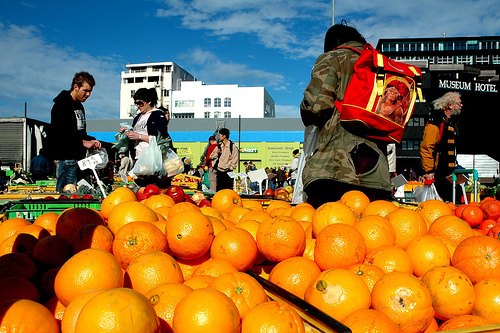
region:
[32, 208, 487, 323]
a lot of oranges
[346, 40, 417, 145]
a red and yellow book bag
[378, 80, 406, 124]
a character from Small Soldiers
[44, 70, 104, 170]
a man in a black hoodie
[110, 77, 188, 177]
a woman carrying several bags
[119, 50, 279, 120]
a white building in the background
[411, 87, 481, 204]
a old man holding grocery bags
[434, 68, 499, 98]
a sign reading Museum Hotel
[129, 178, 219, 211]
a few red apples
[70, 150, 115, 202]
a small white sign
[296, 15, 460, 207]
man with red back pack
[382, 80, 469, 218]
man holding plastic bag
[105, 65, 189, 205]
lady holding plastic bags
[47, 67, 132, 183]
man holding plastic bag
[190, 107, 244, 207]
man looking around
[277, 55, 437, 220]
man has hole in jacket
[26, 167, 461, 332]
oranges in cartons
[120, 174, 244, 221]
apples in cartons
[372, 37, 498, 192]
hotel in background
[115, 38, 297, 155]
white building in background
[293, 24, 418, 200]
man with a backpack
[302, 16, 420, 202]
man with a red backpack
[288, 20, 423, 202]
man wearing a brown jacket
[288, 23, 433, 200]
man with a black patch at the bottom of jacket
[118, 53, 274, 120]
a white building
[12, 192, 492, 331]
a sizable display of oranges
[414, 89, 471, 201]
a man with long gray hair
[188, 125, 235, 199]
a man carrying a child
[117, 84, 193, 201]
a woman with a purse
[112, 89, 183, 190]
woman conducting a transaction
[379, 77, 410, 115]
Picture decal on the red back pack.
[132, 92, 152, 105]
Black sunglasses worn by the woman holding the plastic bags.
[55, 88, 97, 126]
The man wearing a black sweater.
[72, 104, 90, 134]
The white design worn by the man in the black long sleeve sweater.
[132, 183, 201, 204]
The pile of apples in front of the oranges.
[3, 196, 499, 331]
The large pile of oranges.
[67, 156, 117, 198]
The white price sign with the number 8 on it.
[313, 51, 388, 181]
The army fatigue jacket worn by the man carrying the red back pack.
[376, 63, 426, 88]
The two black snaps on the red back pack.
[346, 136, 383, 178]
The whole in the man's fatigue jacket.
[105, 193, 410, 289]
piles of oranges in baskets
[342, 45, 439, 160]
red and yellow graphic back pack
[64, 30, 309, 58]
blue and white cloudy sky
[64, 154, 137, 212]
81A white sign for produce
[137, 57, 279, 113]
wide square shaped buiding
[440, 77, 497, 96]
Museum Hotel white sign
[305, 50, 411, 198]
camo jacket on woman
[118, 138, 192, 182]
white plastic grocery bags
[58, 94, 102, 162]
black mens graphic hoodie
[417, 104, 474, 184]
orange and black mens striped jacket